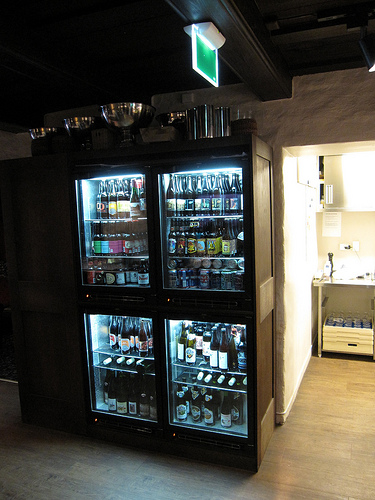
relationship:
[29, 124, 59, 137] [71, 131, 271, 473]
bowl sitting on refrigerator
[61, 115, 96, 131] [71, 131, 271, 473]
bowl sitting on refrigerator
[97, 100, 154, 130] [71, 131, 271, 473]
bowl sitting on refrigerator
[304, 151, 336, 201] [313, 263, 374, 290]
cabinet hanging above a counter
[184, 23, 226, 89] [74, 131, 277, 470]
sign over cooler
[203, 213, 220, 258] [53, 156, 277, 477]
liquor bottle in cooler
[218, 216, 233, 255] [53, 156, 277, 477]
liquor bottle in cooler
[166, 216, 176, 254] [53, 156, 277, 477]
liquor bottle in cooler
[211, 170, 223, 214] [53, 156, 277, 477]
liquor bottle in cooler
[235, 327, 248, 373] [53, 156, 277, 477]
liquor bottle in cooler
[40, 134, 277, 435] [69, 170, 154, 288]
cooler has door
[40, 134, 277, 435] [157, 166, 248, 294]
cooler has door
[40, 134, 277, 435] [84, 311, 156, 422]
cooler has door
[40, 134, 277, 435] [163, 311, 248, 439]
cooler has door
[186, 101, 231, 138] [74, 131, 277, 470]
metal pot on cooler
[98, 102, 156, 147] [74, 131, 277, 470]
bowl on cooler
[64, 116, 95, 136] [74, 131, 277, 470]
bowl on cooler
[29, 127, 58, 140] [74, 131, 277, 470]
bowl on cooler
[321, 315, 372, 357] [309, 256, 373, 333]
drawer under counter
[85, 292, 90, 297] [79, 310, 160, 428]
light on door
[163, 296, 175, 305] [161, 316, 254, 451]
light on door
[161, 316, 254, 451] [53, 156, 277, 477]
door of cooler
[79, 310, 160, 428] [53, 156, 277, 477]
door of cooler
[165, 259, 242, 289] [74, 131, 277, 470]
cans in cooler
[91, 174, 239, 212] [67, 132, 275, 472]
bottles sitting on top shelf of cooler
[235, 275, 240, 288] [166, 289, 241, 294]
can stacked on shelf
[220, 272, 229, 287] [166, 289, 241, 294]
can stacked on shelf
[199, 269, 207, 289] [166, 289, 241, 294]
can stacked on shelf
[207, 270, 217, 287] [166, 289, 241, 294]
can stacked on shelf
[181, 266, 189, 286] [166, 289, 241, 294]
can stacked on shelf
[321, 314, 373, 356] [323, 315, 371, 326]
crate filled with items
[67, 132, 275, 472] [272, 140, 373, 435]
cooler near a doorway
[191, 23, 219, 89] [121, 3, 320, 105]
sign on ceiling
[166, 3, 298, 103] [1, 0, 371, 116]
beams across ceiling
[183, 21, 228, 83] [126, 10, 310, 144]
light on ceiling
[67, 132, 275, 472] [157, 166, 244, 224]
cooler with beverages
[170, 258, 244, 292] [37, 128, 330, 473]
cans on a shelf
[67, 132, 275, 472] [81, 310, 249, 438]
cooler on top of other freezer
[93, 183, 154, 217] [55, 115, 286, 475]
beer in freezer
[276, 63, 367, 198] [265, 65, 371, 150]
paper piece on wall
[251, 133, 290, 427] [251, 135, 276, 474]
door on door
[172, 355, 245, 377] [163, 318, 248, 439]
shelf in freezer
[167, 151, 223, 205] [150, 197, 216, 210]
bottle with label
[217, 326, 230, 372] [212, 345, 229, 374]
bottle with label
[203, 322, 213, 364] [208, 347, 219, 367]
bottle with white label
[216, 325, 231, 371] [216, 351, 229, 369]
bottle with white label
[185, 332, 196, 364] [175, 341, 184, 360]
bottle with white label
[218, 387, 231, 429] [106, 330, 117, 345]
bottle with white label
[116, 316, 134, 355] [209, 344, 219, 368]
bottle with white label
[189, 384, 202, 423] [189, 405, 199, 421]
bottle with white label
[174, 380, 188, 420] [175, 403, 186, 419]
bottle with lable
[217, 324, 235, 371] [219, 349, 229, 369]
bottle with label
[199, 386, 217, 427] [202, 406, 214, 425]
bottle with label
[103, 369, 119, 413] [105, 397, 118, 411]
bottle with label